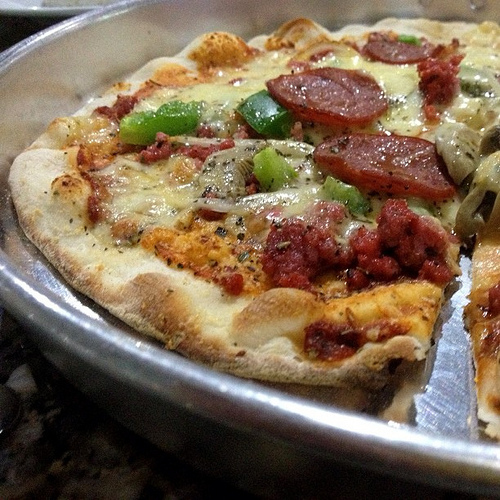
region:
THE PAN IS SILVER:
[0, 0, 498, 494]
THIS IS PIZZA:
[6, 15, 498, 453]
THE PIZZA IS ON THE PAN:
[3, 9, 498, 444]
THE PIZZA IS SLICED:
[8, 12, 498, 444]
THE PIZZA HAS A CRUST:
[2, 13, 499, 440]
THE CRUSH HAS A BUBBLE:
[218, 286, 333, 343]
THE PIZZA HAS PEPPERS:
[108, 76, 378, 236]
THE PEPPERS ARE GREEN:
[114, 90, 373, 220]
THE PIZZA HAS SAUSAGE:
[264, 195, 456, 299]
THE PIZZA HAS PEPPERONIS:
[262, 58, 455, 203]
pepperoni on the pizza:
[306, 65, 346, 121]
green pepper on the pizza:
[126, 105, 176, 125]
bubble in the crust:
[242, 292, 297, 336]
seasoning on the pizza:
[211, 154, 252, 266]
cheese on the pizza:
[121, 184, 159, 216]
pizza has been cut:
[423, 390, 464, 450]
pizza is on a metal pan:
[17, 35, 61, 81]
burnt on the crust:
[202, 31, 248, 63]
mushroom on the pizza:
[465, 175, 487, 225]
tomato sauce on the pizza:
[155, 133, 216, 158]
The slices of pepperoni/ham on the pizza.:
[273, 54, 460, 203]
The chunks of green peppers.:
[123, 78, 371, 217]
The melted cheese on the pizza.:
[83, 48, 498, 278]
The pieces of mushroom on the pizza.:
[436, 105, 498, 241]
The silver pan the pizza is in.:
[1, 3, 498, 470]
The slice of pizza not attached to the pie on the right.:
[466, 193, 498, 425]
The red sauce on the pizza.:
[252, 211, 452, 298]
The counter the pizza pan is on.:
[0, 343, 229, 495]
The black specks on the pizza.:
[72, 41, 478, 342]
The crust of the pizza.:
[30, 12, 473, 320]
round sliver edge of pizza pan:
[260, 404, 477, 464]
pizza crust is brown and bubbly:
[135, 292, 300, 341]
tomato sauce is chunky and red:
[351, 204, 436, 280]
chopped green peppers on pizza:
[121, 96, 282, 137]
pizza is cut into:
[407, 237, 499, 335]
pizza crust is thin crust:
[267, 279, 439, 390]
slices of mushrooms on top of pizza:
[436, 120, 491, 221]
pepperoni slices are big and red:
[271, 68, 436, 193]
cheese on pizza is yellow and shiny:
[114, 164, 176, 214]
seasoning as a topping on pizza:
[175, 150, 255, 269]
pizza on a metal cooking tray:
[4, 2, 497, 485]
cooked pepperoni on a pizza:
[257, 59, 395, 128]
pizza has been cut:
[387, 155, 493, 430]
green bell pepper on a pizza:
[112, 95, 207, 152]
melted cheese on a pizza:
[92, 146, 255, 248]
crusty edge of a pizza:
[102, 261, 432, 402]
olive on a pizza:
[447, 171, 498, 239]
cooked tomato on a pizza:
[257, 194, 449, 294]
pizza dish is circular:
[0, 7, 493, 497]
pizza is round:
[7, 74, 499, 442]